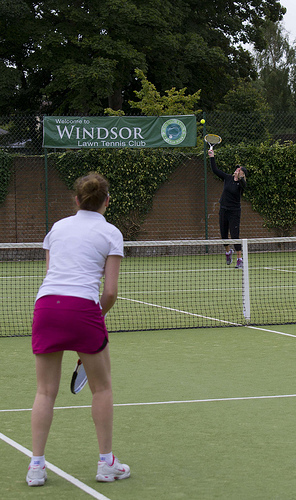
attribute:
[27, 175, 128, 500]
woman — playing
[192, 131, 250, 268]
woman — serving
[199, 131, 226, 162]
racket — yellow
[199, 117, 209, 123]
ball — yellow, flying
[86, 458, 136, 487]
shoe — pink, white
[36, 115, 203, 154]
banner — green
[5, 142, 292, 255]
fence — tall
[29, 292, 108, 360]
skirt — pink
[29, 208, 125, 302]
shirt — white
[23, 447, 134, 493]
shoes — white, pink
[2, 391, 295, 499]
lines — white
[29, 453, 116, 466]
socks — white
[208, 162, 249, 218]
shirt — black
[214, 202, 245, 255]
pants — black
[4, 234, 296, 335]
net — white